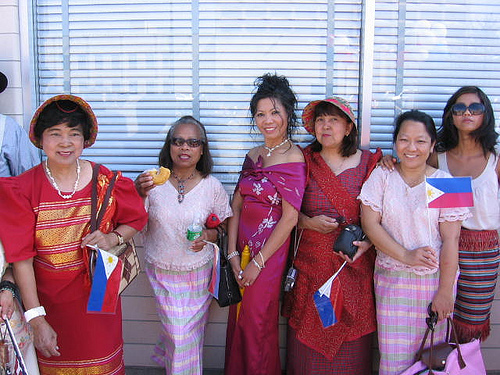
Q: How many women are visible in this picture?
A: Six.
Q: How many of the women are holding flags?
A: Four.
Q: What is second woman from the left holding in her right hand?
A: Donut.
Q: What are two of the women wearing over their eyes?
A: Sunglasses.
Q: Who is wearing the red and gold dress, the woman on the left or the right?
A: Left.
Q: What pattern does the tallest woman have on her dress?
A: Flowers.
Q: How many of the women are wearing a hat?
A: Two.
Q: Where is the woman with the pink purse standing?
A: On the right.